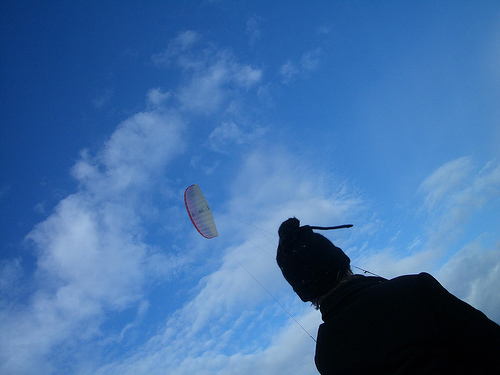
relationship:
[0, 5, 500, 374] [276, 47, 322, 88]
sky with cloud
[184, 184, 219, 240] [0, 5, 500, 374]
parasailing flying in sky